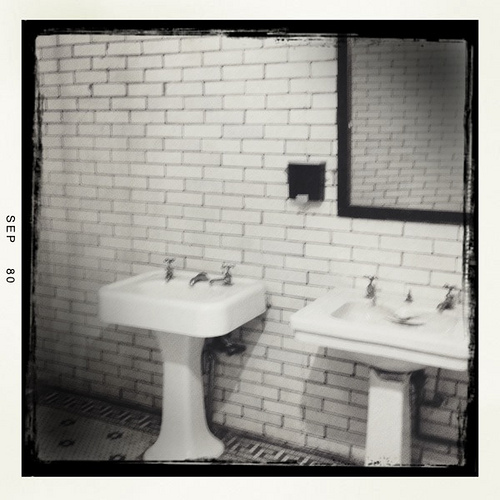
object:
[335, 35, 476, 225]
wall inmirror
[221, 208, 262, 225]
brick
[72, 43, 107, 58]
brick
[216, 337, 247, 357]
pipes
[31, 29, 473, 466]
wall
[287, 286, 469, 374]
sink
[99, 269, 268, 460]
sink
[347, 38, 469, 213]
mirror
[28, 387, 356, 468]
floor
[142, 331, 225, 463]
pedestal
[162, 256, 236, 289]
fawcets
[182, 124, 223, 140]
brick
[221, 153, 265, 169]
brick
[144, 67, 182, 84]
brick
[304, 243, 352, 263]
brick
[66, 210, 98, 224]
brick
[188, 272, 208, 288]
faucet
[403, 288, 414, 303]
faucet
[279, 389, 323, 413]
brick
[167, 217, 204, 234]
floor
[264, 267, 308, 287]
brick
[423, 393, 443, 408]
pipes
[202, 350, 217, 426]
pipes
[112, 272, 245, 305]
sink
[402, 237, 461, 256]
white brick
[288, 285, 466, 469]
sink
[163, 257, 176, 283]
faucet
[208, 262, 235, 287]
faucet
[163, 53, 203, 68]
white brick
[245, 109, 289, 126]
brick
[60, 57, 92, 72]
brick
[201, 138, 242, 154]
brick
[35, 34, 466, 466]
photo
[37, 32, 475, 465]
bathroom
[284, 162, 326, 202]
soap dispenser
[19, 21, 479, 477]
border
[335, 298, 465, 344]
sink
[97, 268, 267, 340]
sink